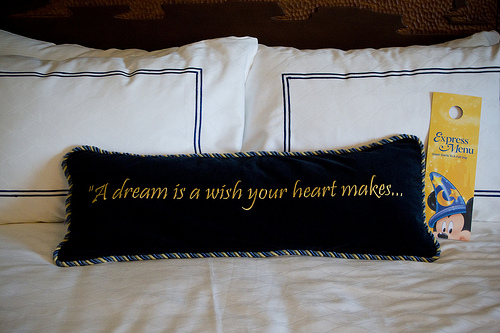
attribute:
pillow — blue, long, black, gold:
[67, 148, 444, 259]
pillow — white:
[260, 39, 499, 212]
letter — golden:
[93, 181, 112, 207]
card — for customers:
[423, 91, 484, 250]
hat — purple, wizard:
[426, 174, 465, 212]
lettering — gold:
[83, 182, 403, 201]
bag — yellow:
[431, 94, 479, 244]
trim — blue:
[274, 63, 498, 83]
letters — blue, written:
[431, 132, 485, 157]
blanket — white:
[2, 264, 493, 333]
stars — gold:
[433, 173, 439, 185]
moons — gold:
[436, 190, 455, 206]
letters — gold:
[85, 183, 393, 199]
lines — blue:
[274, 70, 496, 79]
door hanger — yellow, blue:
[420, 91, 475, 236]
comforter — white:
[5, 227, 499, 320]